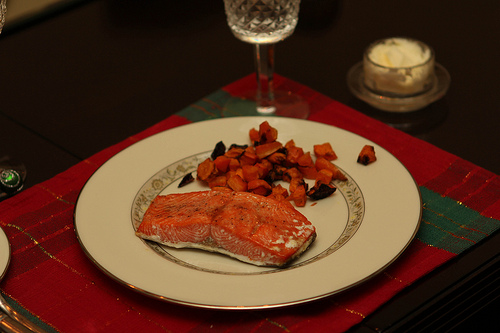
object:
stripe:
[1, 226, 74, 287]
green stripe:
[414, 212, 484, 242]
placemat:
[2, 69, 500, 333]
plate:
[72, 115, 424, 309]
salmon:
[136, 189, 316, 266]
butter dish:
[359, 36, 436, 98]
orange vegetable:
[313, 141, 337, 160]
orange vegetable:
[292, 185, 307, 207]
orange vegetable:
[297, 150, 312, 167]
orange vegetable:
[196, 158, 214, 180]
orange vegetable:
[227, 173, 246, 192]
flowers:
[208, 206, 256, 244]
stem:
[251, 41, 276, 112]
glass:
[224, 0, 298, 113]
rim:
[72, 114, 422, 310]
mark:
[1, 170, 22, 191]